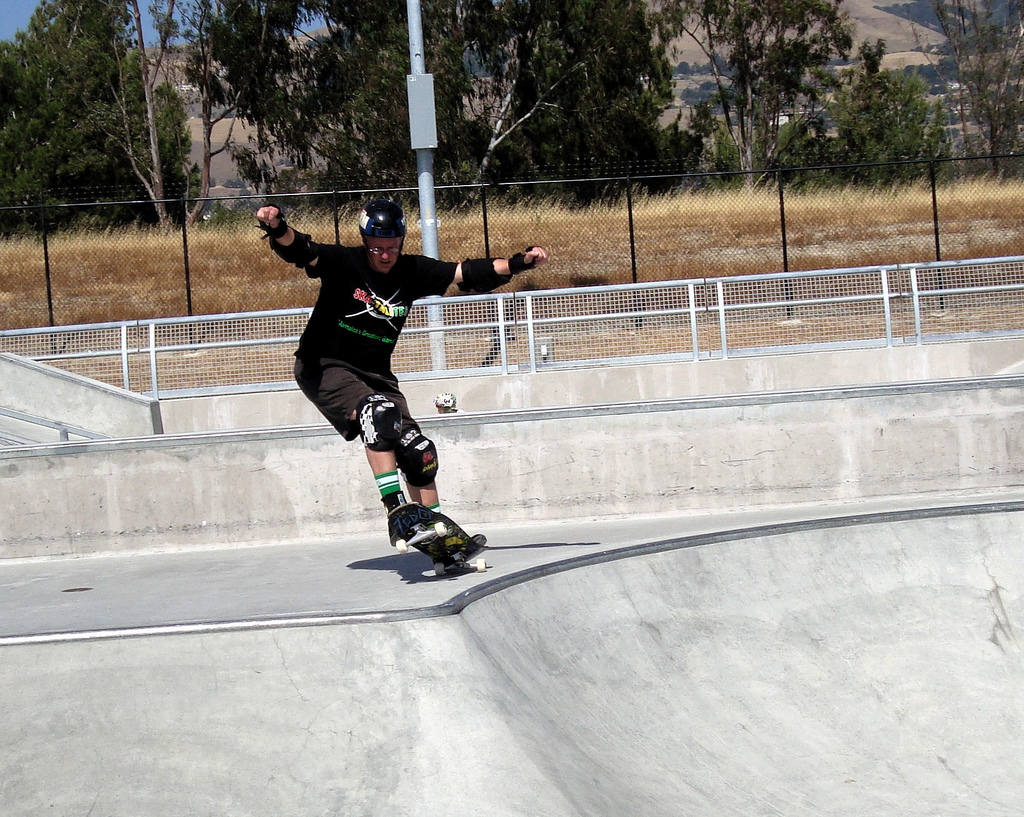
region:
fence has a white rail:
[142, 312, 159, 392]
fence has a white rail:
[120, 322, 130, 387]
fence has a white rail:
[493, 297, 503, 362]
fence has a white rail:
[522, 300, 539, 365]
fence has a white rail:
[681, 278, 702, 354]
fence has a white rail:
[712, 283, 729, 344]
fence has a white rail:
[876, 267, 893, 344]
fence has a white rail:
[908, 261, 922, 334]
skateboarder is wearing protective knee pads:
[391, 418, 445, 485]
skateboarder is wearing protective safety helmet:
[353, 192, 408, 265]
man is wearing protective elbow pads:
[460, 249, 530, 298]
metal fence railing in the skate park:
[550, 246, 1022, 380]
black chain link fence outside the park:
[569, 145, 1022, 264]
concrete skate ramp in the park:
[0, 569, 1022, 814]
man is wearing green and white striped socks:
[369, 462, 405, 507]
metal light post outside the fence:
[407, 3, 445, 253]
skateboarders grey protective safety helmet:
[430, 388, 465, 417]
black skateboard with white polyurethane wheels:
[384, 497, 492, 581]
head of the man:
[340, 174, 445, 289]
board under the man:
[344, 478, 525, 618]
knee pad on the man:
[322, 386, 422, 482]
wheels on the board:
[370, 499, 504, 608]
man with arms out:
[168, 146, 612, 485]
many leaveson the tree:
[536, 18, 698, 116]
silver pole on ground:
[353, 34, 491, 190]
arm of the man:
[426, 193, 576, 358]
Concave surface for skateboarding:
[2, 515, 1023, 811]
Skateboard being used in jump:
[381, 499, 489, 575]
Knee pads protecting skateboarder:
[353, 392, 443, 476]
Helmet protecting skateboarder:
[353, 198, 410, 244]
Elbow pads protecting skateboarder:
[271, 230, 502, 292]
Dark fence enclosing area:
[2, 148, 1020, 352]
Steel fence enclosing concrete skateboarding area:
[2, 252, 1017, 395]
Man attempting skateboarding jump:
[250, 195, 548, 570]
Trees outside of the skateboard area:
[5, 42, 1014, 202]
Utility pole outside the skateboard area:
[400, 2, 448, 364]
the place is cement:
[0, 328, 1019, 813]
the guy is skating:
[253, 205, 547, 578]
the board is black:
[392, 501, 485, 559]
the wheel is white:
[434, 520, 448, 536]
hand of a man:
[253, 204, 277, 231]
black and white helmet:
[355, 202, 403, 237]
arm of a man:
[446, 252, 524, 292]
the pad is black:
[460, 258, 508, 290]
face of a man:
[365, 232, 400, 270]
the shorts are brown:
[295, 349, 410, 445]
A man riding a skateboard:
[252, 203, 548, 514]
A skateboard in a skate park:
[385, 500, 493, 571]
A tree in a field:
[828, 61, 946, 189]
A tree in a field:
[660, 105, 731, 197]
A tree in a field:
[520, 2, 714, 203]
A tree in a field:
[455, 19, 599, 226]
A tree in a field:
[117, 74, 194, 237]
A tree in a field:
[8, 8, 174, 239]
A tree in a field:
[828, 40, 946, 183]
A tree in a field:
[682, 98, 717, 137]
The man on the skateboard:
[247, 195, 549, 551]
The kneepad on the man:
[356, 387, 404, 446]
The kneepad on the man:
[395, 423, 440, 487]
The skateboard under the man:
[388, 494, 488, 570]